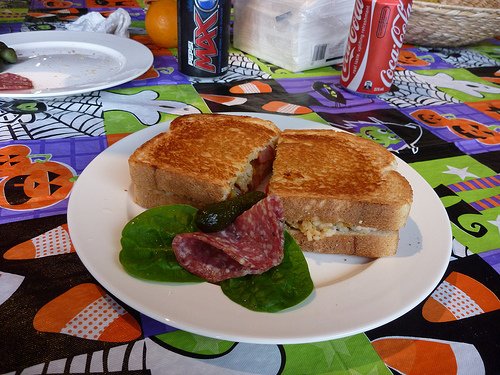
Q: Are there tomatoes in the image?
A: No, there are no tomatoes.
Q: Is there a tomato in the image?
A: No, there are no tomatoes.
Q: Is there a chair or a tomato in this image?
A: No, there are no tomatoes or chairs.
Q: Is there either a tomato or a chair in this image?
A: No, there are no tomatoes or chairs.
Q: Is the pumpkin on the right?
A: Yes, the pumpkin is on the right of the image.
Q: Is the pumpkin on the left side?
A: No, the pumpkin is on the right of the image.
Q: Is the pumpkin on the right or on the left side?
A: The pumpkin is on the right of the image.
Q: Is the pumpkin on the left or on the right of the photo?
A: The pumpkin is on the right of the image.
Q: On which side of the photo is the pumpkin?
A: The pumpkin is on the right of the image.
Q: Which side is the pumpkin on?
A: The pumpkin is on the right of the image.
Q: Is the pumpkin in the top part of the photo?
A: Yes, the pumpkin is in the top of the image.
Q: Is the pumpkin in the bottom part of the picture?
A: No, the pumpkin is in the top of the image.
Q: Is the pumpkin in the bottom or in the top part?
A: The pumpkin is in the top of the image.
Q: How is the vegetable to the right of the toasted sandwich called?
A: The vegetable is a pumpkin.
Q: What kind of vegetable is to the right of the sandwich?
A: The vegetable is a pumpkin.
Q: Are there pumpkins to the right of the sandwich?
A: Yes, there is a pumpkin to the right of the sandwich.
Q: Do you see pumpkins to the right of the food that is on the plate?
A: Yes, there is a pumpkin to the right of the sandwich.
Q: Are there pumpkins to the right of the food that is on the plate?
A: Yes, there is a pumpkin to the right of the sandwich.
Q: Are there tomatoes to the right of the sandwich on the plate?
A: No, there is a pumpkin to the right of the sandwich.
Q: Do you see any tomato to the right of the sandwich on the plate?
A: No, there is a pumpkin to the right of the sandwich.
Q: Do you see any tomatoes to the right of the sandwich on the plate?
A: No, there is a pumpkin to the right of the sandwich.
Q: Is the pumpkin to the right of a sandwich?
A: Yes, the pumpkin is to the right of a sandwich.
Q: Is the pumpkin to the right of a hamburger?
A: No, the pumpkin is to the right of a sandwich.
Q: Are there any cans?
A: Yes, there is a can.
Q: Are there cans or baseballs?
A: Yes, there is a can.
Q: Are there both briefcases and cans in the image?
A: No, there is a can but no briefcases.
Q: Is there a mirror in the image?
A: No, there are no mirrors.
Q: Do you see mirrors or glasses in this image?
A: No, there are no mirrors or glasses.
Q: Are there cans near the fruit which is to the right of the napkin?
A: Yes, there is a can near the fruit.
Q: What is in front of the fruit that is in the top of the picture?
A: The can is in front of the fruit.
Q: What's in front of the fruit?
A: The can is in front of the fruit.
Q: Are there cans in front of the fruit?
A: Yes, there is a can in front of the fruit.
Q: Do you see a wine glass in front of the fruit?
A: No, there is a can in front of the fruit.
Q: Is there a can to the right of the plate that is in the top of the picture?
A: Yes, there is a can to the right of the plate.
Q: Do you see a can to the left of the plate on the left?
A: No, the can is to the right of the plate.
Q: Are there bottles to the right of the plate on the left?
A: No, there is a can to the right of the plate.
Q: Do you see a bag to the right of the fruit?
A: No, there is a can to the right of the fruit.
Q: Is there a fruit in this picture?
A: Yes, there is a fruit.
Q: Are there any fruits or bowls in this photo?
A: Yes, there is a fruit.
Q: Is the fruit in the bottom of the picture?
A: No, the fruit is in the top of the image.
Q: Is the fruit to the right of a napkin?
A: Yes, the fruit is to the right of a napkin.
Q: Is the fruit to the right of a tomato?
A: No, the fruit is to the right of a napkin.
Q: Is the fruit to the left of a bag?
A: No, the fruit is to the left of the can.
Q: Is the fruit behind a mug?
A: No, the fruit is behind the can.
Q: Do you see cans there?
A: Yes, there is a can.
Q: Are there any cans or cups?
A: Yes, there is a can.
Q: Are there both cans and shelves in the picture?
A: No, there is a can but no shelves.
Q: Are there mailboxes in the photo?
A: No, there are no mailboxes.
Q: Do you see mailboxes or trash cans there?
A: No, there are no mailboxes or trash cans.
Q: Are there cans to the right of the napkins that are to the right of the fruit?
A: Yes, there is a can to the right of the napkins.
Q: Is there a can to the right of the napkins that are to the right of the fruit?
A: Yes, there is a can to the right of the napkins.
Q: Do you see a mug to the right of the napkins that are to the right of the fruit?
A: No, there is a can to the right of the napkins.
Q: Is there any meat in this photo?
A: Yes, there is meat.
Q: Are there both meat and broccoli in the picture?
A: No, there is meat but no broccoli.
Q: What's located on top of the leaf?
A: The meat is on top of the leaf.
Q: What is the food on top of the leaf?
A: The food is meat.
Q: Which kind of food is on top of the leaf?
A: The food is meat.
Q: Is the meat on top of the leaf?
A: Yes, the meat is on top of the leaf.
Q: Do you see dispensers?
A: No, there are no dispensers.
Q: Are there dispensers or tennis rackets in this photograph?
A: No, there are no dispensers or tennis rackets.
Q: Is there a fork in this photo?
A: No, there are no forks.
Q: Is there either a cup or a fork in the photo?
A: No, there are no forks or cups.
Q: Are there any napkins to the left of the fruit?
A: Yes, there is a napkin to the left of the fruit.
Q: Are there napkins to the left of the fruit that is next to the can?
A: Yes, there is a napkin to the left of the fruit.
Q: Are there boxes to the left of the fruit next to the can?
A: No, there is a napkin to the left of the fruit.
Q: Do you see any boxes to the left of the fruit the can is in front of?
A: No, there is a napkin to the left of the fruit.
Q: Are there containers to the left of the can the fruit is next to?
A: No, there is a napkin to the left of the can.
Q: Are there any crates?
A: No, there are no crates.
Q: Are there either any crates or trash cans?
A: No, there are no crates or trash cans.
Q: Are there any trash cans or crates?
A: No, there are no crates or trash cans.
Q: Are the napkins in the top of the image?
A: Yes, the napkins are in the top of the image.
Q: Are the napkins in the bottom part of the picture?
A: No, the napkins are in the top of the image.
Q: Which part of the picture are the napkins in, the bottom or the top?
A: The napkins are in the top of the image.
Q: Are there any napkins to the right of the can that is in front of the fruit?
A: Yes, there are napkins to the right of the can.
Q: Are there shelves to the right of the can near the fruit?
A: No, there are napkins to the right of the can.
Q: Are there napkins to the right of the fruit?
A: Yes, there are napkins to the right of the fruit.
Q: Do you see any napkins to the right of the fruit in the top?
A: Yes, there are napkins to the right of the fruit.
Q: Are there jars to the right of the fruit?
A: No, there are napkins to the right of the fruit.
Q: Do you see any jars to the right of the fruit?
A: No, there are napkins to the right of the fruit.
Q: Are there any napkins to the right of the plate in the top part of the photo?
A: Yes, there are napkins to the right of the plate.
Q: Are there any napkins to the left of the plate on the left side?
A: No, the napkins are to the right of the plate.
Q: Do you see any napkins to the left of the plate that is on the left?
A: No, the napkins are to the right of the plate.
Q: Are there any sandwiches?
A: Yes, there is a sandwich.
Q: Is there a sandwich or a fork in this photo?
A: Yes, there is a sandwich.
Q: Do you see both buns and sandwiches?
A: No, there is a sandwich but no buns.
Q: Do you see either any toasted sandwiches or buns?
A: Yes, there is a toasted sandwich.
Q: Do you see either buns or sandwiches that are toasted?
A: Yes, the sandwich is toasted.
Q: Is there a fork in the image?
A: No, there are no forks.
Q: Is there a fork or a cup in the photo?
A: No, there are no forks or cups.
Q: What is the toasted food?
A: The food is a sandwich.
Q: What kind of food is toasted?
A: The food is a sandwich.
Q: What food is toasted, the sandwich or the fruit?
A: The sandwich is toasted.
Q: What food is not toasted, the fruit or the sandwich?
A: The fruit is not toasted.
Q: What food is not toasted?
A: The food is a fruit.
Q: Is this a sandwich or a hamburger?
A: This is a sandwich.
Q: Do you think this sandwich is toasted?
A: Yes, the sandwich is toasted.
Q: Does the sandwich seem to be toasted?
A: Yes, the sandwich is toasted.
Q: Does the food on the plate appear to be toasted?
A: Yes, the sandwich is toasted.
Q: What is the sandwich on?
A: The sandwich is on the plate.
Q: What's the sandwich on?
A: The sandwich is on the plate.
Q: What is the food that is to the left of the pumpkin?
A: The food is a sandwich.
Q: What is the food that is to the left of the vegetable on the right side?
A: The food is a sandwich.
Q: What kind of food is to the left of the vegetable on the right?
A: The food is a sandwich.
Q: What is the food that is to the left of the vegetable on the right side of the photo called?
A: The food is a sandwich.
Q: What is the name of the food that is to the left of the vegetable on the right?
A: The food is a sandwich.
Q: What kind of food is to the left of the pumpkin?
A: The food is a sandwich.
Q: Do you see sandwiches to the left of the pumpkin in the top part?
A: Yes, there is a sandwich to the left of the pumpkin.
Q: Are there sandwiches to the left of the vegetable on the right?
A: Yes, there is a sandwich to the left of the pumpkin.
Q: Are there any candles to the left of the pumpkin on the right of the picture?
A: No, there is a sandwich to the left of the pumpkin.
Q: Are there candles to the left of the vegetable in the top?
A: No, there is a sandwich to the left of the pumpkin.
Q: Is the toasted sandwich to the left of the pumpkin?
A: Yes, the sandwich is to the left of the pumpkin.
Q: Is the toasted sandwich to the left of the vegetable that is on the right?
A: Yes, the sandwich is to the left of the pumpkin.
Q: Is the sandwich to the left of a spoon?
A: No, the sandwich is to the left of the pumpkin.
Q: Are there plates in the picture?
A: Yes, there is a plate.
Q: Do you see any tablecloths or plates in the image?
A: Yes, there is a plate.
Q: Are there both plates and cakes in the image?
A: No, there is a plate but no cakes.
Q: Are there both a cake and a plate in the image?
A: No, there is a plate but no cakes.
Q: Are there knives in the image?
A: No, there are no knives.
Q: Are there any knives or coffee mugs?
A: No, there are no knives or coffee mugs.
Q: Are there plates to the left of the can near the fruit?
A: Yes, there is a plate to the left of the can.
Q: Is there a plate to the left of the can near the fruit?
A: Yes, there is a plate to the left of the can.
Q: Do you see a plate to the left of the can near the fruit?
A: Yes, there is a plate to the left of the can.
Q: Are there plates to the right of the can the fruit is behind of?
A: No, the plate is to the left of the can.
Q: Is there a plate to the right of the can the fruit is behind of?
A: No, the plate is to the left of the can.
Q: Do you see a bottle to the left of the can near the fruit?
A: No, there is a plate to the left of the can.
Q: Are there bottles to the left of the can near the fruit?
A: No, there is a plate to the left of the can.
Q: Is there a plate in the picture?
A: Yes, there is a plate.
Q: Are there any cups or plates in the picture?
A: Yes, there is a plate.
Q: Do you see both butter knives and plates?
A: No, there is a plate but no butter knives.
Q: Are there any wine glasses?
A: No, there are no wine glasses.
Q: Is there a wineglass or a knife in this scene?
A: No, there are no wine glasses or knives.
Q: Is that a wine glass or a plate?
A: That is a plate.